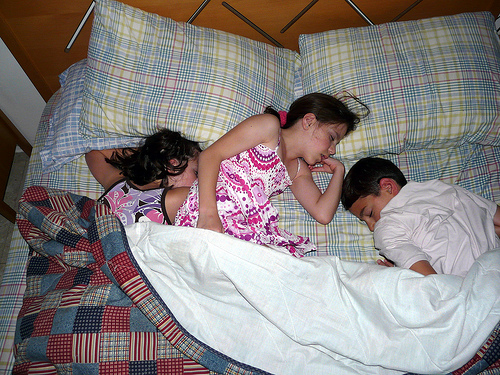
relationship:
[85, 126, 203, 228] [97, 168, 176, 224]
girl wearing purple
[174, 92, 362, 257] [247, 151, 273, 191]
girl wearing pink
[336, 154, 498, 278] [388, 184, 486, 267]
boy in shirt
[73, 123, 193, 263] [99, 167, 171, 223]
girl in shirt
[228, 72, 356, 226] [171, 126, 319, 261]
girl in dress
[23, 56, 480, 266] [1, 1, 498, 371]
sheets on bed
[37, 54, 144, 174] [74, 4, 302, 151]
small pillow under big pillow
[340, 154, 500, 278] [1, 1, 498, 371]
boy sleeping on bed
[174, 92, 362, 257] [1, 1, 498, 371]
girl sleeping on bed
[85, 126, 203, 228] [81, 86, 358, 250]
girl sleeping on kids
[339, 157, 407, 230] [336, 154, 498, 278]
head on boy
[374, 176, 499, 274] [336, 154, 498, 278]
shirt on boy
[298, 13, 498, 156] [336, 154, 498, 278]
pillow above boy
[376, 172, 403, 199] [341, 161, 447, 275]
ear on boy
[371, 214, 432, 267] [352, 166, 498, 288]
sleeve on shirt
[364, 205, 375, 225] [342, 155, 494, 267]
eyes on boy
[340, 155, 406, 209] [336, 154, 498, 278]
hair belonging to boy